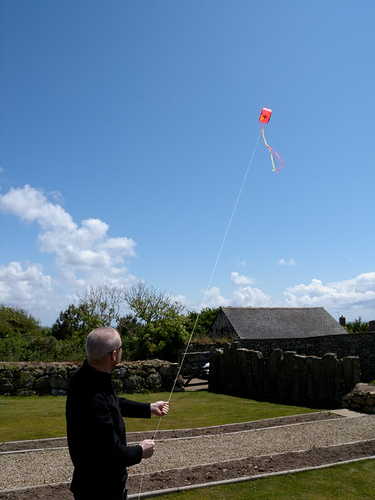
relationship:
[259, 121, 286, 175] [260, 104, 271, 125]
strings attached to kite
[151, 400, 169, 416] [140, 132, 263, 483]
hand holding kite string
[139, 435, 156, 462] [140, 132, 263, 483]
hand holding kite string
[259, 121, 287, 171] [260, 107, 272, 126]
strings on kite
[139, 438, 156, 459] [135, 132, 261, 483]
hand hold kite string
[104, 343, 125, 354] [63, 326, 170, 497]
sunglasses on man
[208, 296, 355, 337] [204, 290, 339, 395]
roof of building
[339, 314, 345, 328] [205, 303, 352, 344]
chimney poking out of roof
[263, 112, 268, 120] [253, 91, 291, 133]
cross on kite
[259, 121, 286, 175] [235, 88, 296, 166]
strings on kite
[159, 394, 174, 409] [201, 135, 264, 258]
hand holding string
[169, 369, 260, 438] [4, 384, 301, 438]
grass on surface